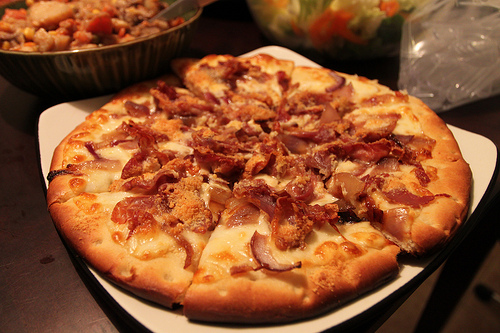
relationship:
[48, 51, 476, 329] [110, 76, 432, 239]
pizza has top